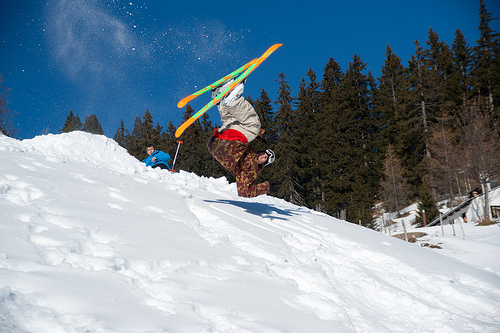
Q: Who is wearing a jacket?
A: The man is wearing a jacket.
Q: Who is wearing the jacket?
A: The man is wearing a jacket.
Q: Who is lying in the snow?
A: The man is lying in the snow.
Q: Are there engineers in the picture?
A: No, there are no engineers.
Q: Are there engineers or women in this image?
A: No, there are no engineers or women.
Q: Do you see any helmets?
A: No, there are no helmets.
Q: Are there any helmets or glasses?
A: No, there are no helmets or glasses.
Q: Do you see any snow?
A: Yes, there is snow.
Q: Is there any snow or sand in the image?
A: Yes, there is snow.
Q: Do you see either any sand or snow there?
A: Yes, there is snow.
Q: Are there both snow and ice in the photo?
A: No, there is snow but no ice.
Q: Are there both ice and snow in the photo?
A: No, there is snow but no ice.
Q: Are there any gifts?
A: No, there are no gifts.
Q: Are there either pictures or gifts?
A: No, there are no gifts or pictures.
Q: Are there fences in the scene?
A: No, there are no fences.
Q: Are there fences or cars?
A: No, there are no fences or cars.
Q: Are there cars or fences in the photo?
A: No, there are no fences or cars.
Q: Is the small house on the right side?
A: Yes, the house is on the right of the image.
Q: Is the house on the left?
A: No, the house is on the right of the image.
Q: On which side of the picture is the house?
A: The house is on the right of the image.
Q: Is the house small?
A: Yes, the house is small.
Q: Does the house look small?
A: Yes, the house is small.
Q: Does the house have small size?
A: Yes, the house is small.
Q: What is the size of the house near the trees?
A: The house is small.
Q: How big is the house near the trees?
A: The house is small.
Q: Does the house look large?
A: No, the house is small.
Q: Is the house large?
A: No, the house is small.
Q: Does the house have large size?
A: No, the house is small.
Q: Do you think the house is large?
A: No, the house is small.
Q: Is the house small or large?
A: The house is small.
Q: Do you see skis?
A: Yes, there are skis.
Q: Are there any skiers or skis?
A: Yes, there are skis.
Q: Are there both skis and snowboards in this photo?
A: No, there are skis but no snowboards.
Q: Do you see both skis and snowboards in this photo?
A: No, there are skis but no snowboards.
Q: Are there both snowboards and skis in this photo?
A: No, there are skis but no snowboards.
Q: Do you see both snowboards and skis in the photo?
A: No, there are skis but no snowboards.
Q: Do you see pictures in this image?
A: No, there are no pictures.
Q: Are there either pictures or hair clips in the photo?
A: No, there are no pictures or hair clips.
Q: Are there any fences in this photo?
A: No, there are no fences.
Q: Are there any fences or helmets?
A: No, there are no fences or helmets.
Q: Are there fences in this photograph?
A: No, there are no fences.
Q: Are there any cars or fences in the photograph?
A: No, there are no fences or cars.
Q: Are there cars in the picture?
A: No, there are no cars.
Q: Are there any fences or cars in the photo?
A: No, there are no cars or fences.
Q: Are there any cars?
A: No, there are no cars.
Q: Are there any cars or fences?
A: No, there are no cars or fences.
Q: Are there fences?
A: No, there are no fences.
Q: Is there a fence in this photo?
A: No, there are no fences.